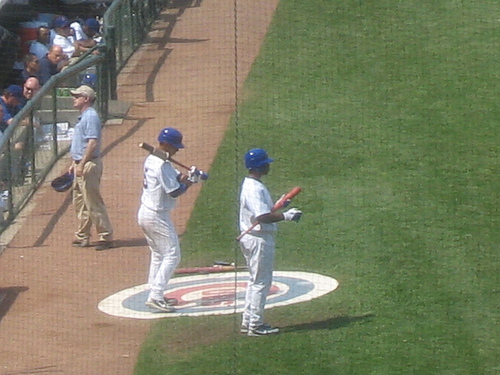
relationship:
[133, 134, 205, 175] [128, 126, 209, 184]
baseball player holding bat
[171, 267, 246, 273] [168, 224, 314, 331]
baseball bat on ground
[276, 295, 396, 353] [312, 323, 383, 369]
shadow on grass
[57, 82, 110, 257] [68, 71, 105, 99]
man wearing baseball cap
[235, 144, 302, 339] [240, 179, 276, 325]
man wearing uniform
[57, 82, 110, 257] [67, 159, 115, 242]
man wearing pants